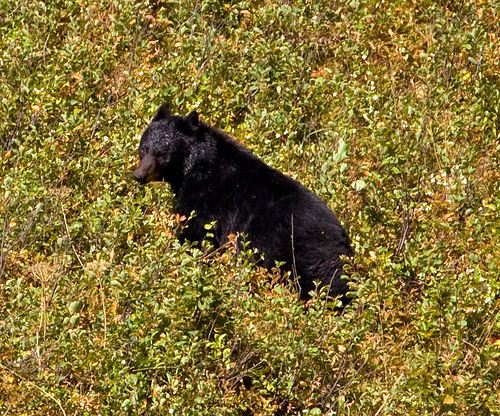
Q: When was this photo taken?
A: Day time.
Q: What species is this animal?
A: Bear.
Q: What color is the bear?
A: Black.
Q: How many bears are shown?
A: One.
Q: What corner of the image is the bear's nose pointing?
A: Lower left.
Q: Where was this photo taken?
A: A field.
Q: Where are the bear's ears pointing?
A: Upward.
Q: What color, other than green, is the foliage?
A: Yellow.